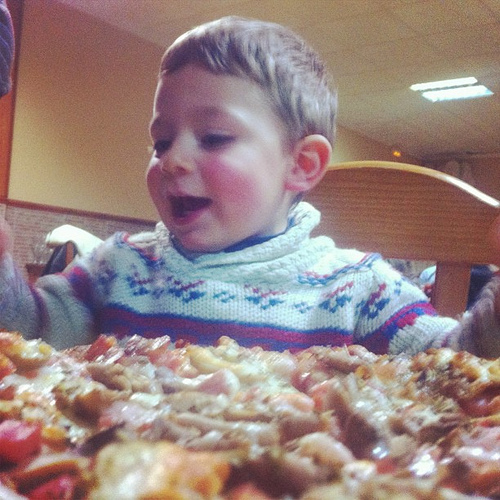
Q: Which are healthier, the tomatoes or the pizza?
A: The tomatoes are healthier than the pizza.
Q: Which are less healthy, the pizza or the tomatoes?
A: The pizza are less healthy than the tomatoes.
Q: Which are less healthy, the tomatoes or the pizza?
A: The pizza are less healthy than the tomatoes.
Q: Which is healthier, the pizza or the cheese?
A: The cheese is healthier than the pizza.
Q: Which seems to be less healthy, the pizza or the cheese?
A: The pizza is less healthy than the cheese.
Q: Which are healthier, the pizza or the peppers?
A: The peppers are healthier than the pizza.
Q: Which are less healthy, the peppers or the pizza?
A: The pizza are less healthy than the peppers.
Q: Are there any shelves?
A: No, there are no shelves.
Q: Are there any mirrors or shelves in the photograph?
A: No, there are no shelves or mirrors.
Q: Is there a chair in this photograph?
A: Yes, there is a chair.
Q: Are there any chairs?
A: Yes, there is a chair.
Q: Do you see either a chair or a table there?
A: Yes, there is a chair.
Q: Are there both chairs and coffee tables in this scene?
A: No, there is a chair but no coffee tables.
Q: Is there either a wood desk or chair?
A: Yes, there is a wood chair.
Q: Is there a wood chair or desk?
A: Yes, there is a wood chair.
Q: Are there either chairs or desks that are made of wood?
A: Yes, the chair is made of wood.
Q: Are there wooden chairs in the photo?
A: Yes, there is a wood chair.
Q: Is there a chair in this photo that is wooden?
A: Yes, there is a chair that is wooden.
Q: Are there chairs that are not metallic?
A: Yes, there is a wooden chair.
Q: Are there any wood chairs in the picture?
A: Yes, there is a chair that is made of wood.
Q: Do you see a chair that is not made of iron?
A: Yes, there is a chair that is made of wood.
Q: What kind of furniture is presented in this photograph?
A: The furniture is a chair.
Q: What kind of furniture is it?
A: The piece of furniture is a chair.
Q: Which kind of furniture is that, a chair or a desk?
A: This is a chair.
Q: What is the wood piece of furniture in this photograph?
A: The piece of furniture is a chair.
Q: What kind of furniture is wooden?
A: The furniture is a chair.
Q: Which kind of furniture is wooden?
A: The furniture is a chair.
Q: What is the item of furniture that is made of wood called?
A: The piece of furniture is a chair.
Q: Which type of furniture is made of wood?
A: The furniture is a chair.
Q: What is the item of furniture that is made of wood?
A: The piece of furniture is a chair.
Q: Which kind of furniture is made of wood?
A: The furniture is a chair.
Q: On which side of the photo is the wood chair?
A: The chair is on the right of the image.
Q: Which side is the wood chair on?
A: The chair is on the right of the image.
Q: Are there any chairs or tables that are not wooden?
A: No, there is a chair but it is wooden.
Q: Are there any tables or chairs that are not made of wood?
A: No, there is a chair but it is made of wood.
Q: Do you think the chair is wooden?
A: Yes, the chair is wooden.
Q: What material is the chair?
A: The chair is made of wood.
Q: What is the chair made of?
A: The chair is made of wood.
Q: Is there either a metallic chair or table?
A: No, there is a chair but it is wooden.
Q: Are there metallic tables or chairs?
A: No, there is a chair but it is wooden.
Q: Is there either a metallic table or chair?
A: No, there is a chair but it is wooden.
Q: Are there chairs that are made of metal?
A: No, there is a chair but it is made of wood.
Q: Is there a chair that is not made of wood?
A: No, there is a chair but it is made of wood.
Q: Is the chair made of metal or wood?
A: The chair is made of wood.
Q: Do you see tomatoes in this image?
A: Yes, there are tomatoes.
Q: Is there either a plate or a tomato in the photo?
A: Yes, there are tomatoes.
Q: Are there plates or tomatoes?
A: Yes, there are tomatoes.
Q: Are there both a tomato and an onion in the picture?
A: Yes, there are both a tomato and an onion.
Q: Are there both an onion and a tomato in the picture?
A: Yes, there are both a tomato and an onion.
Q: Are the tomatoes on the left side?
A: Yes, the tomatoes are on the left of the image.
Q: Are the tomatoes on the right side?
A: No, the tomatoes are on the left of the image.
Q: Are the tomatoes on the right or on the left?
A: The tomatoes are on the left of the image.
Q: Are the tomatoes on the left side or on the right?
A: The tomatoes are on the left of the image.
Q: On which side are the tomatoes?
A: The tomatoes are on the left of the image.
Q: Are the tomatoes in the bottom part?
A: Yes, the tomatoes are in the bottom of the image.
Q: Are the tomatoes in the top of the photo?
A: No, the tomatoes are in the bottom of the image.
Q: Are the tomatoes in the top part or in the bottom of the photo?
A: The tomatoes are in the bottom of the image.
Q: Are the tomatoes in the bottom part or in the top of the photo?
A: The tomatoes are in the bottom of the image.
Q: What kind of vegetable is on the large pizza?
A: The vegetables are tomatoes.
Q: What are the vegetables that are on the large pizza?
A: The vegetables are tomatoes.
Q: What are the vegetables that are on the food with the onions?
A: The vegetables are tomatoes.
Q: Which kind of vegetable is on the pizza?
A: The vegetables are tomatoes.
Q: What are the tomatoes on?
A: The tomatoes are on the pizza.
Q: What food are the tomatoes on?
A: The tomatoes are on the pizza.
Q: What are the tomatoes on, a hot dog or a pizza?
A: The tomatoes are on a pizza.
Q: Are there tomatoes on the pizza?
A: Yes, there are tomatoes on the pizza.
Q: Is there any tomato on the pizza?
A: Yes, there are tomatoes on the pizza.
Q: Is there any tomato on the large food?
A: Yes, there are tomatoes on the pizza.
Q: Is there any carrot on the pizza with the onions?
A: No, there are tomatoes on the pizza.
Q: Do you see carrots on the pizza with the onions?
A: No, there are tomatoes on the pizza.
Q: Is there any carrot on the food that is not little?
A: No, there are tomatoes on the pizza.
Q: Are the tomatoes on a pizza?
A: Yes, the tomatoes are on a pizza.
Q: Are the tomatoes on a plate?
A: No, the tomatoes are on a pizza.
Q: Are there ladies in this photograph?
A: No, there are no ladies.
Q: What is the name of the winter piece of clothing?
A: The clothing item is a sweater.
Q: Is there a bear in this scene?
A: No, there are no bears.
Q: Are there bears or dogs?
A: No, there are no bears or dogs.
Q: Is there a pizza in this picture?
A: Yes, there is a pizza.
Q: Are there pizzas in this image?
A: Yes, there is a pizza.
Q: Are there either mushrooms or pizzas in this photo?
A: Yes, there is a pizza.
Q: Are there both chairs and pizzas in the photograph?
A: Yes, there are both a pizza and a chair.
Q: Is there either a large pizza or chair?
A: Yes, there is a large pizza.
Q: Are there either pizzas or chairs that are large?
A: Yes, the pizza is large.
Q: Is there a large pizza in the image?
A: Yes, there is a large pizza.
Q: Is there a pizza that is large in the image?
A: Yes, there is a large pizza.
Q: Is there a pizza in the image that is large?
A: Yes, there is a pizza that is large.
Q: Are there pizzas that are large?
A: Yes, there is a pizza that is large.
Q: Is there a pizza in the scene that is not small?
A: Yes, there is a large pizza.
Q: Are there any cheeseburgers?
A: No, there are no cheeseburgers.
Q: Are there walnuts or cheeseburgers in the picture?
A: No, there are no cheeseburgers or walnuts.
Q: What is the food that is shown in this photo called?
A: The food is a pizza.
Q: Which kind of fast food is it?
A: The food is a pizza.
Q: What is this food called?
A: This is a pizza.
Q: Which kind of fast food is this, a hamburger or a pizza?
A: This is a pizza.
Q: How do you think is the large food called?
A: The food is a pizza.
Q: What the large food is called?
A: The food is a pizza.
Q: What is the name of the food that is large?
A: The food is a pizza.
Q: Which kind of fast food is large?
A: The fast food is a pizza.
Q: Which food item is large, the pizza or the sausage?
A: The pizza is large.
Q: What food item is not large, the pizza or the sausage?
A: The sausage is not large.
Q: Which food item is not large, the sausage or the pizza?
A: The sausage is not large.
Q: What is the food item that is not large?
A: The food item is a sausage.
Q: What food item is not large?
A: The food item is a sausage.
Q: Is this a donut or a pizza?
A: This is a pizza.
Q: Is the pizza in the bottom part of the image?
A: Yes, the pizza is in the bottom of the image.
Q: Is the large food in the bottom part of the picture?
A: Yes, the pizza is in the bottom of the image.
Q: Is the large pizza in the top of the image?
A: No, the pizza is in the bottom of the image.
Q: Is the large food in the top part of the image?
A: No, the pizza is in the bottom of the image.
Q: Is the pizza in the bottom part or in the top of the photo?
A: The pizza is in the bottom of the image.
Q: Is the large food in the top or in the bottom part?
A: The pizza is in the bottom of the image.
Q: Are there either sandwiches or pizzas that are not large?
A: No, there is a pizza but it is large.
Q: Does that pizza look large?
A: Yes, the pizza is large.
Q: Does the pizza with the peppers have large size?
A: Yes, the pizza is large.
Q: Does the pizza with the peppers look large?
A: Yes, the pizza is large.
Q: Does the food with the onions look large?
A: Yes, the pizza is large.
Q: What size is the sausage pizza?
A: The pizza is large.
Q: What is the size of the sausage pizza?
A: The pizza is large.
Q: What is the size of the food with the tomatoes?
A: The pizza is large.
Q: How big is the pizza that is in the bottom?
A: The pizza is large.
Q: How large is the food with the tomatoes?
A: The pizza is large.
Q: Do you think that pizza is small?
A: No, the pizza is large.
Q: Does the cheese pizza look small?
A: No, the pizza is large.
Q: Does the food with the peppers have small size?
A: No, the pizza is large.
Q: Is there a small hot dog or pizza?
A: No, there is a pizza but it is large.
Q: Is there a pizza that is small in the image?
A: No, there is a pizza but it is large.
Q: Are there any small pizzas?
A: No, there is a pizza but it is large.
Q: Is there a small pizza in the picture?
A: No, there is a pizza but it is large.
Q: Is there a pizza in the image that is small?
A: No, there is a pizza but it is large.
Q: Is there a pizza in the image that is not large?
A: No, there is a pizza but it is large.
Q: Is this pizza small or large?
A: The pizza is large.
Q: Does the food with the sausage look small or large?
A: The pizza is large.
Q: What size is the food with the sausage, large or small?
A: The pizza is large.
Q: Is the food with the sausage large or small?
A: The pizza is large.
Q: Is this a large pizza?
A: Yes, this is a large pizza.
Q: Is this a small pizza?
A: No, this is a large pizza.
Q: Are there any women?
A: No, there are no women.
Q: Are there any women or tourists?
A: No, there are no women or tourists.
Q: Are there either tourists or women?
A: No, there are no women or tourists.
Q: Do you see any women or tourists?
A: No, there are no women or tourists.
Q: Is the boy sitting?
A: Yes, the boy is sitting.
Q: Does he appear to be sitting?
A: Yes, the boy is sitting.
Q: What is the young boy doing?
A: The boy is sitting.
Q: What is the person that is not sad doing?
A: The boy is sitting.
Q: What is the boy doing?
A: The boy is sitting.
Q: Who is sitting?
A: The boy is sitting.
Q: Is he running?
A: No, the boy is sitting.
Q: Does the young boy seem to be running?
A: No, the boy is sitting.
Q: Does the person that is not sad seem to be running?
A: No, the boy is sitting.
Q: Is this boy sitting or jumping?
A: The boy is sitting.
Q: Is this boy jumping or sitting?
A: The boy is sitting.